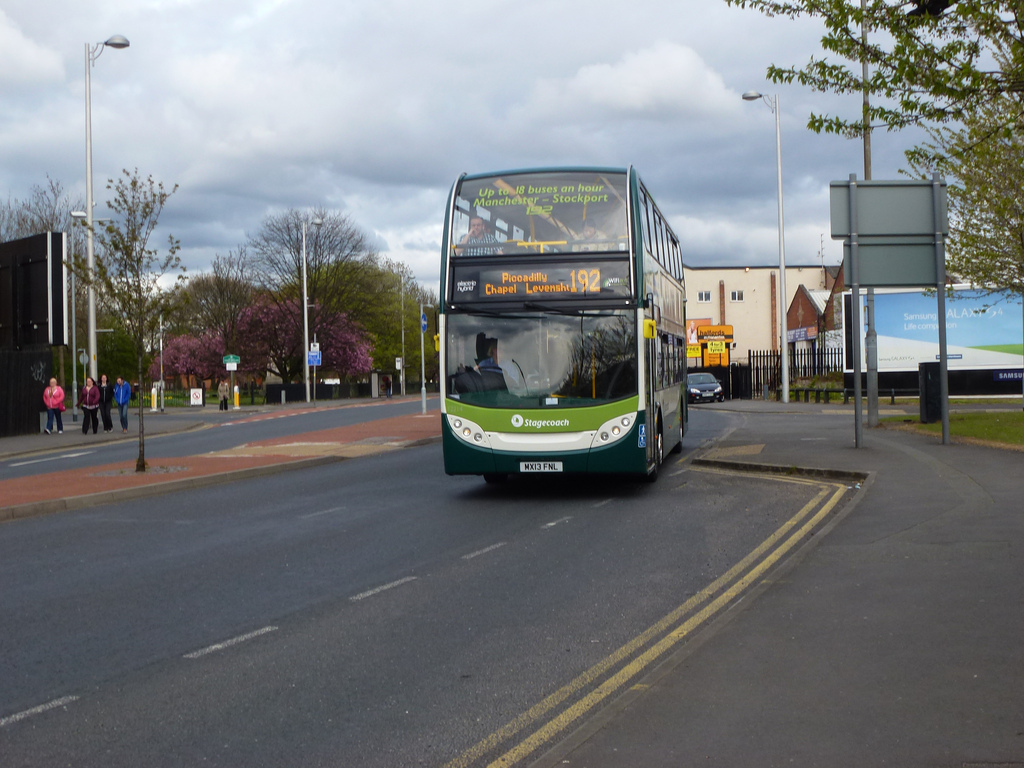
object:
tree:
[87, 208, 194, 458]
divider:
[43, 456, 229, 499]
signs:
[826, 181, 950, 285]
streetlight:
[263, 201, 339, 411]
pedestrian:
[115, 379, 131, 432]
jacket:
[112, 380, 131, 404]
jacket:
[76, 384, 101, 408]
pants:
[80, 409, 97, 434]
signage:
[699, 324, 734, 364]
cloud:
[525, 70, 709, 127]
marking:
[317, 521, 497, 591]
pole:
[770, 63, 797, 429]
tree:
[271, 206, 403, 416]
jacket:
[43, 386, 65, 407]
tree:
[147, 310, 223, 399]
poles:
[844, 190, 872, 446]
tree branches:
[214, 207, 398, 393]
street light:
[80, 32, 132, 381]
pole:
[82, 39, 98, 362]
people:
[43, 377, 67, 435]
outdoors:
[0, 0, 1024, 768]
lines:
[351, 137, 698, 503]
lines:
[665, 578, 745, 632]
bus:
[440, 167, 689, 490]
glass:
[454, 193, 599, 360]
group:
[564, 266, 600, 292]